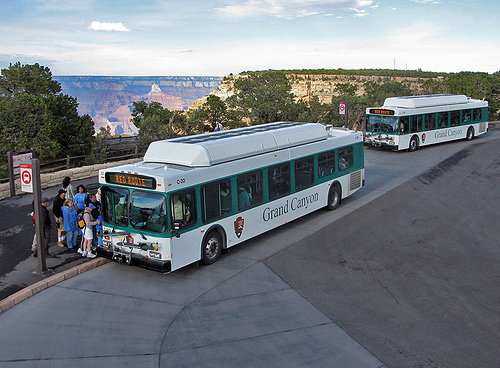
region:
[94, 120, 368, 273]
this is a bus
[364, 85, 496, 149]
this is a bus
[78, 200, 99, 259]
this is a girl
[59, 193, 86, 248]
this is a girl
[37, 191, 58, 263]
this is a girl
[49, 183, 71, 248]
this is a girl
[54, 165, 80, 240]
this is a girl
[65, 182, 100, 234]
this is a girl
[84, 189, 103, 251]
this is a girl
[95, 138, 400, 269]
bus on a street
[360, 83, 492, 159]
bus on a street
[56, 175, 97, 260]
people getting on bus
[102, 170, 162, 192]
sign on a bus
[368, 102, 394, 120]
sign on a bus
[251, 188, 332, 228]
sign on a bus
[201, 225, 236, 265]
tire on a bus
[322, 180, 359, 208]
tire on a bus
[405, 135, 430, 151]
tire on a bus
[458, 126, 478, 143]
tire on a bus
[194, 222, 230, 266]
The left front wheel of a tour bus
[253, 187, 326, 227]
Grand Canyon written on a tour bus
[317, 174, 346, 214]
The left rear wheel of a tour bus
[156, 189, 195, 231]
A driver sitting in a tour bus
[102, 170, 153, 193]
Red Route sign on the front of a bus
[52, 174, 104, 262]
People getting on a tour bus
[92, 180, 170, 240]
The front window of a tour bus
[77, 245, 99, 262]
a person wearing white shoes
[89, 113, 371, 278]
A tour bus at the grand canyon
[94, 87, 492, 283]
two tour buses at the Grand Canyon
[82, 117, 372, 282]
Grand Canyon tour bus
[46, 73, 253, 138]
The Grand Canyon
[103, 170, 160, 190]
Red Route bus sign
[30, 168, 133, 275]
Tourists waiting in line to board the tour bus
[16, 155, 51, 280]
Red route bus stop sign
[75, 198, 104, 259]
Elderly man wearing a black and yellow backpack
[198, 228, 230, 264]
Large black bus tire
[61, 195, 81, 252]
Female wearing a blue jacket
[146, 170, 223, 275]
Bus driver in driver's seat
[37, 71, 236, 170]
Grand Canyon overlook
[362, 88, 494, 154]
The bus is green and white.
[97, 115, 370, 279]
The bus is green and white.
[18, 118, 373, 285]
People are boarding the bus.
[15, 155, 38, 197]
The sign is red and white.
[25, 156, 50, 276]
The signpost is brown.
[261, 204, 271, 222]
The letter is green.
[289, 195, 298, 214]
The letter is green.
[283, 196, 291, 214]
The letter is green.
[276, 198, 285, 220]
The letter is green.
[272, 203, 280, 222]
The letter is green.